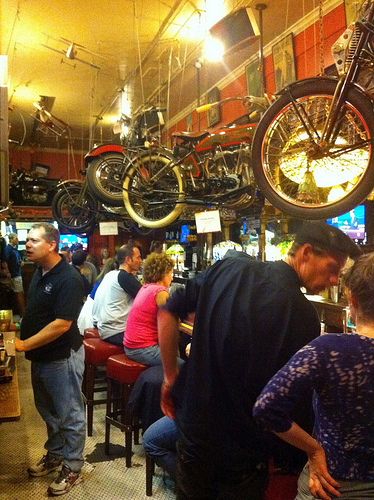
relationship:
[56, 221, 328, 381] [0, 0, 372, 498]
people in bar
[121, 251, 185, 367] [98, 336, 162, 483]
woman sitting on stool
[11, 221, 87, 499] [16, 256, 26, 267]
man holding beer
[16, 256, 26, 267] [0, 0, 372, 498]
beer in a bar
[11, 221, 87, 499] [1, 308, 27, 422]
man standing at bar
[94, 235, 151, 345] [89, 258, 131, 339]
man wearing shirt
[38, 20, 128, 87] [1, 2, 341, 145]
airplane hanging from ceiling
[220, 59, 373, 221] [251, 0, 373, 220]
tire on motorbike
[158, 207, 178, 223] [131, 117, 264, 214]
tire on motor bike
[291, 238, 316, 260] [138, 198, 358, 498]
ear on man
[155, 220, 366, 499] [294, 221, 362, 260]
man wearing hat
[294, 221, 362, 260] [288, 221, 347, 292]
hat on head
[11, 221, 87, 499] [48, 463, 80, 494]
man wearing shoe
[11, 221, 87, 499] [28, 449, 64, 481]
man wearing shoe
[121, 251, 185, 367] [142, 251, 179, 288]
woman has hair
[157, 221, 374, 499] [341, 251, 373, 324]
woman has hair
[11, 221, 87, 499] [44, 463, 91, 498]
man wearing shoe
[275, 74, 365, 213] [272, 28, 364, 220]
wheel on bike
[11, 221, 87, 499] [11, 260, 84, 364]
man wearing shirt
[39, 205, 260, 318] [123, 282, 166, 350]
woman's wearing tank top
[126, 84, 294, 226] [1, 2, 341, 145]
motorcycle hanging from ceiling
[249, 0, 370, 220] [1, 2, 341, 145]
motorcycle hanging from ceiling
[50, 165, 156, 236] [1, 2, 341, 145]
motorcycle hanging from ceiling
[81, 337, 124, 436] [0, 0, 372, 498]
stool at bar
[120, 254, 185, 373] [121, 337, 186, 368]
woman wearing blue jeans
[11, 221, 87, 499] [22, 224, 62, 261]
man has head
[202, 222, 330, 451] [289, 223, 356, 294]
man has head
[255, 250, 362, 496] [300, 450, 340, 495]
woman has hand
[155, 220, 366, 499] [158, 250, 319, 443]
man wearing shirt